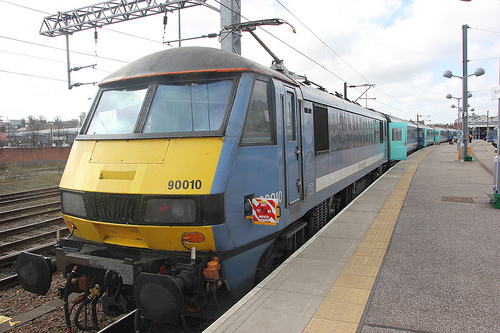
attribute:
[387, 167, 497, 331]
platform — paved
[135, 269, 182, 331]
bumper — black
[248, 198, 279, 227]
sign — red, white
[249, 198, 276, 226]
sign — flipped out 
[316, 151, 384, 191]
stripe — white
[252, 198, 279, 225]
sign — red, white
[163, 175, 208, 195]
numbers — black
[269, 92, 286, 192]
door — blue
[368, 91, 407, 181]
door — open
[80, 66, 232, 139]
windshield — large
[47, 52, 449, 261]
train — yellow, black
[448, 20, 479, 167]
pole — gray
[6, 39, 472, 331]
train — blue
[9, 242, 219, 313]
bumper — black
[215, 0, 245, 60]
pole — gray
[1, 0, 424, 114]
power line — Electric 